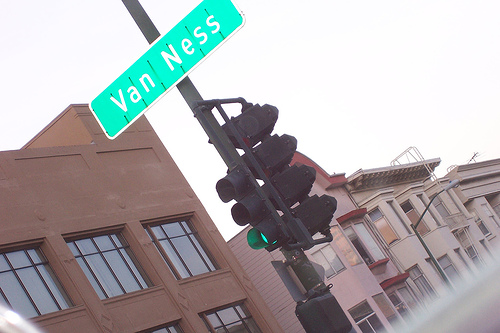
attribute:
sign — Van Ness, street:
[85, 3, 252, 132]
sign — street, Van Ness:
[68, 6, 275, 145]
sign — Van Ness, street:
[76, 6, 263, 128]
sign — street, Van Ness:
[76, 3, 264, 141]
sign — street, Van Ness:
[76, 12, 261, 146]